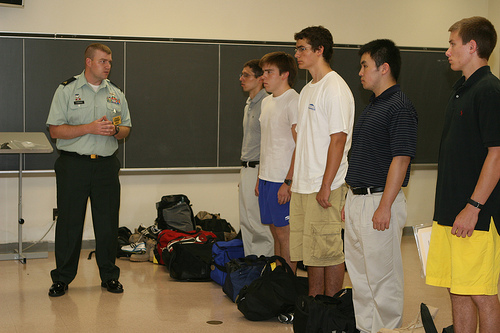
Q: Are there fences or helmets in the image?
A: No, there are no helmets or fences.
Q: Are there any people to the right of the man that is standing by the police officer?
A: Yes, there is a person to the right of the man.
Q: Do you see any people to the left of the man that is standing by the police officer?
A: No, the person is to the right of the man.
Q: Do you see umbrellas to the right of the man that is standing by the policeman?
A: No, there is a person to the right of the man.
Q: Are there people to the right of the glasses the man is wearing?
A: Yes, there is a person to the right of the glasses.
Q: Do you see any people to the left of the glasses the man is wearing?
A: No, the person is to the right of the glasses.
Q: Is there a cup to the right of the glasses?
A: No, there is a person to the right of the glasses.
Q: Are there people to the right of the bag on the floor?
A: Yes, there is a person to the right of the bag.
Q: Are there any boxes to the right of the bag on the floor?
A: No, there is a person to the right of the bag.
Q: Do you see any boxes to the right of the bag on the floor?
A: No, there is a person to the right of the bag.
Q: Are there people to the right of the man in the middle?
A: Yes, there is a person to the right of the man.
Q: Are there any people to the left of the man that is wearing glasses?
A: No, the person is to the right of the man.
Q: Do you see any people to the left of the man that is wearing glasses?
A: No, the person is to the right of the man.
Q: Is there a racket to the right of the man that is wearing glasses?
A: No, there is a person to the right of the man.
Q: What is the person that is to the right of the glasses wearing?
A: The person is wearing a belt.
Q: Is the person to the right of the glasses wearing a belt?
A: Yes, the person is wearing a belt.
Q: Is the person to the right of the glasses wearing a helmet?
A: No, the person is wearing a belt.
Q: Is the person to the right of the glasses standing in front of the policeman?
A: Yes, the person is standing in front of the policeman.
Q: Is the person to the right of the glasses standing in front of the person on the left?
A: Yes, the person is standing in front of the policeman.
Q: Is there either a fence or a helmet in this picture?
A: No, there are no fences or helmets.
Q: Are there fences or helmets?
A: No, there are no fences or helmets.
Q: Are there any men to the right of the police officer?
A: Yes, there is a man to the right of the police officer.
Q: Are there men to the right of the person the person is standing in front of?
A: Yes, there is a man to the right of the police officer.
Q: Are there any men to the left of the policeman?
A: No, the man is to the right of the policeman.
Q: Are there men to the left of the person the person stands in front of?
A: No, the man is to the right of the policeman.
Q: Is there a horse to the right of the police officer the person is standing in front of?
A: No, there is a man to the right of the police officer.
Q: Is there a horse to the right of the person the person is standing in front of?
A: No, there is a man to the right of the police officer.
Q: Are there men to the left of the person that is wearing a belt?
A: Yes, there is a man to the left of the person.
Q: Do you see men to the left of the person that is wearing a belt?
A: Yes, there is a man to the left of the person.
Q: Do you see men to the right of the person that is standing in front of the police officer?
A: No, the man is to the left of the person.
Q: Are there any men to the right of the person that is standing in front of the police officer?
A: No, the man is to the left of the person.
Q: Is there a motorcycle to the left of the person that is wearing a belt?
A: No, there is a man to the left of the person.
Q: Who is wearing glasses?
A: The man is wearing glasses.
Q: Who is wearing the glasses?
A: The man is wearing glasses.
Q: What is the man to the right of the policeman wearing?
A: The man is wearing glasses.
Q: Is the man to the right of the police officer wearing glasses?
A: Yes, the man is wearing glasses.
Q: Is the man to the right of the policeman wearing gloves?
A: No, the man is wearing glasses.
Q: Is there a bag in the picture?
A: Yes, there is a bag.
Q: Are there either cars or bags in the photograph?
A: Yes, there is a bag.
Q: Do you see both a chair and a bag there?
A: No, there is a bag but no chairs.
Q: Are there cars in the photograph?
A: No, there are no cars.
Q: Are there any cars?
A: No, there are no cars.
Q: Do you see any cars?
A: No, there are no cars.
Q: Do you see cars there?
A: No, there are no cars.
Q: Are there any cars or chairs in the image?
A: No, there are no cars or chairs.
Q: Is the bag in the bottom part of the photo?
A: Yes, the bag is in the bottom of the image.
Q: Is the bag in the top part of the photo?
A: No, the bag is in the bottom of the image.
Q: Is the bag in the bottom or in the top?
A: The bag is in the bottom of the image.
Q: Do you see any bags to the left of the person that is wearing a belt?
A: Yes, there is a bag to the left of the person.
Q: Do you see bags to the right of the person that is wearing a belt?
A: No, the bag is to the left of the person.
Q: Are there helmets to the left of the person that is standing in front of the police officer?
A: No, there is a bag to the left of the person.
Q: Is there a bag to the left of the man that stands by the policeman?
A: Yes, there is a bag to the left of the man.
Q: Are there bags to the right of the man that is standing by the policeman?
A: No, the bag is to the left of the man.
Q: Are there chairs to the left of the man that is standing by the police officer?
A: No, there is a bag to the left of the man.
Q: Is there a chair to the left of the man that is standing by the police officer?
A: No, there is a bag to the left of the man.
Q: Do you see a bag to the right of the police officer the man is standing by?
A: Yes, there is a bag to the right of the policeman.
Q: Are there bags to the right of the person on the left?
A: Yes, there is a bag to the right of the policeman.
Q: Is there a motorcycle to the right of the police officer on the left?
A: No, there is a bag to the right of the police officer.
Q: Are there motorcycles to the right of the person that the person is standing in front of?
A: No, there is a bag to the right of the police officer.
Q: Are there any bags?
A: Yes, there is a bag.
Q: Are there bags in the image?
A: Yes, there is a bag.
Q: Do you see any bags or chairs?
A: Yes, there is a bag.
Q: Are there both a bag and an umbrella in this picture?
A: No, there is a bag but no umbrellas.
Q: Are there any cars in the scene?
A: No, there are no cars.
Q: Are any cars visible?
A: No, there are no cars.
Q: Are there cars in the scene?
A: No, there are no cars.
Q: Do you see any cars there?
A: No, there are no cars.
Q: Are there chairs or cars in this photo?
A: No, there are no cars or chairs.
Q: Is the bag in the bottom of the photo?
A: Yes, the bag is in the bottom of the image.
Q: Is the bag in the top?
A: No, the bag is in the bottom of the image.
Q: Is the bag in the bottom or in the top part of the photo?
A: The bag is in the bottom of the image.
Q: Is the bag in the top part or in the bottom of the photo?
A: The bag is in the bottom of the image.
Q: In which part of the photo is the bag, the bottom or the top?
A: The bag is in the bottom of the image.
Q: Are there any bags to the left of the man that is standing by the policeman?
A: Yes, there is a bag to the left of the man.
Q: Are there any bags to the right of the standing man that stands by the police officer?
A: No, the bag is to the left of the man.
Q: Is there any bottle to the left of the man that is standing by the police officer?
A: No, there is a bag to the left of the man.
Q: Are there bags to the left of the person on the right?
A: Yes, there is a bag to the left of the person.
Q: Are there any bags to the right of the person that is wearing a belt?
A: No, the bag is to the left of the person.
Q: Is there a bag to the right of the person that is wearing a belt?
A: No, the bag is to the left of the person.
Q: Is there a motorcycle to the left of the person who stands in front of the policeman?
A: No, there is a bag to the left of the person.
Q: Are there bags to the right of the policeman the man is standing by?
A: Yes, there is a bag to the right of the policeman.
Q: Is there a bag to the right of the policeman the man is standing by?
A: Yes, there is a bag to the right of the policeman.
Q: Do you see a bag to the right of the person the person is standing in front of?
A: Yes, there is a bag to the right of the policeman.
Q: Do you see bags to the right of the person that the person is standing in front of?
A: Yes, there is a bag to the right of the policeman.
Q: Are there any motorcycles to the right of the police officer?
A: No, there is a bag to the right of the police officer.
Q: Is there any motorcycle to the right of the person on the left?
A: No, there is a bag to the right of the police officer.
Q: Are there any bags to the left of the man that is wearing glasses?
A: Yes, there is a bag to the left of the man.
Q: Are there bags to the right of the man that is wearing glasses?
A: No, the bag is to the left of the man.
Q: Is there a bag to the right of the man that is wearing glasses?
A: No, the bag is to the left of the man.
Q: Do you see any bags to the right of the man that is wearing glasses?
A: No, the bag is to the left of the man.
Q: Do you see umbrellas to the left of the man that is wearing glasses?
A: No, there is a bag to the left of the man.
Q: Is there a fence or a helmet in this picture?
A: No, there are no fences or helmets.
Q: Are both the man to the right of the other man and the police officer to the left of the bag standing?
A: Yes, both the man and the police officer are standing.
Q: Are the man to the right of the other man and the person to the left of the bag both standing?
A: Yes, both the man and the police officer are standing.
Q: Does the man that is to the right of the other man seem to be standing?
A: Yes, the man is standing.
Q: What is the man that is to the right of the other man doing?
A: The man is standing.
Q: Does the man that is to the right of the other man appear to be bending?
A: No, the man is standing.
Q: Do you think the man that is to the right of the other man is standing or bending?
A: The man is standing.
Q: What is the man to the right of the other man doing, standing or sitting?
A: The man is standing.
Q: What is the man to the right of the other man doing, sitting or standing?
A: The man is standing.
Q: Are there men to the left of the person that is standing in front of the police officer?
A: Yes, there is a man to the left of the person.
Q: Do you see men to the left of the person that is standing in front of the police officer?
A: Yes, there is a man to the left of the person.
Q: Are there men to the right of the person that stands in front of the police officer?
A: No, the man is to the left of the person.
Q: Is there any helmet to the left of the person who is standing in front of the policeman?
A: No, there is a man to the left of the person.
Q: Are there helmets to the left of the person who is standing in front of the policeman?
A: No, there is a man to the left of the person.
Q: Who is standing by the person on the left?
A: The man is standing by the policeman.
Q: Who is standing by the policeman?
A: The man is standing by the policeman.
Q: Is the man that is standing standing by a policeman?
A: Yes, the man is standing by a policeman.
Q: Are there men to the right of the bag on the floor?
A: Yes, there is a man to the right of the bag.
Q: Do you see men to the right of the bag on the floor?
A: Yes, there is a man to the right of the bag.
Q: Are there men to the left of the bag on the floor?
A: No, the man is to the right of the bag.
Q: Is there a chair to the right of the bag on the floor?
A: No, there is a man to the right of the bag.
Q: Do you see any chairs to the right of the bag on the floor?
A: No, there is a man to the right of the bag.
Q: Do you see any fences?
A: No, there are no fences.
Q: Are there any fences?
A: No, there are no fences.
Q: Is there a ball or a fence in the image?
A: No, there are no fences or balls.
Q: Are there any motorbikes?
A: No, there are no motorbikes.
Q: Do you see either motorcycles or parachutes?
A: No, there are no motorcycles or parachutes.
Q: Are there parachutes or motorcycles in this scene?
A: No, there are no motorcycles or parachutes.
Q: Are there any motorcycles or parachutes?
A: No, there are no motorcycles or parachutes.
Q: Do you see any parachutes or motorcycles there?
A: No, there are no motorcycles or parachutes.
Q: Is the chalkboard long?
A: Yes, the chalkboard is long.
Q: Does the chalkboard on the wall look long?
A: Yes, the chalkboard is long.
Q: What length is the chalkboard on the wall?
A: The chalkboard is long.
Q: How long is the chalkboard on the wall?
A: The chalkboard is long.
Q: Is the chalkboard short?
A: No, the chalkboard is long.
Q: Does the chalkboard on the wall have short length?
A: No, the chalkboard is long.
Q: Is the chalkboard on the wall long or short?
A: The chalkboard is long.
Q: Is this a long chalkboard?
A: Yes, this is a long chalkboard.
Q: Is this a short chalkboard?
A: No, this is a long chalkboard.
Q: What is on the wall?
A: The chalkboard is on the wall.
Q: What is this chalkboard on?
A: The chalkboard is on the wall.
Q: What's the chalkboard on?
A: The chalkboard is on the wall.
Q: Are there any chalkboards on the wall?
A: Yes, there is a chalkboard on the wall.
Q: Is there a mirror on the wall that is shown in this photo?
A: No, there is a chalkboard on the wall.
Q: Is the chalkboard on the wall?
A: Yes, the chalkboard is on the wall.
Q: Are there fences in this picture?
A: No, there are no fences.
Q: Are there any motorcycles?
A: No, there are no motorcycles.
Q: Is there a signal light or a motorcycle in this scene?
A: No, there are no motorcycles or traffic lights.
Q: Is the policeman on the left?
A: Yes, the policeman is on the left of the image.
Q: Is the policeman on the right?
A: No, the policeman is on the left of the image.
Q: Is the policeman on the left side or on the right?
A: The policeman is on the left of the image.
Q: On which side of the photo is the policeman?
A: The policeman is on the left of the image.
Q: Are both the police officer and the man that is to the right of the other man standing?
A: Yes, both the police officer and the man are standing.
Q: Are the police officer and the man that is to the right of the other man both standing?
A: Yes, both the police officer and the man are standing.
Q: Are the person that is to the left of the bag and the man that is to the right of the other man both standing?
A: Yes, both the police officer and the man are standing.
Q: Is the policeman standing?
A: Yes, the policeman is standing.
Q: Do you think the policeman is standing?
A: Yes, the policeman is standing.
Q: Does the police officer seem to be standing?
A: Yes, the police officer is standing.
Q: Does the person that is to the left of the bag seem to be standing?
A: Yes, the police officer is standing.